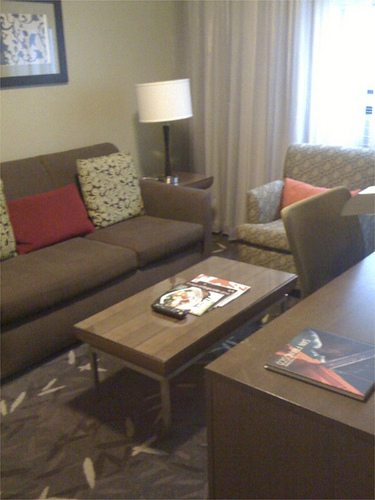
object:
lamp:
[132, 74, 195, 189]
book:
[127, 275, 210, 323]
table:
[59, 242, 301, 446]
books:
[189, 260, 252, 313]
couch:
[6, 128, 215, 355]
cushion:
[76, 189, 206, 267]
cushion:
[0, 164, 139, 324]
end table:
[144, 158, 227, 211]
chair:
[245, 158, 372, 306]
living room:
[4, 8, 368, 498]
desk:
[196, 261, 374, 492]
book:
[262, 318, 375, 406]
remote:
[156, 298, 187, 323]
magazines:
[169, 275, 236, 318]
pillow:
[4, 178, 97, 258]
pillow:
[260, 170, 368, 228]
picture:
[0, 0, 53, 68]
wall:
[7, 3, 186, 158]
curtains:
[185, 1, 312, 239]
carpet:
[15, 397, 157, 499]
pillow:
[75, 148, 148, 230]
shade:
[134, 78, 196, 124]